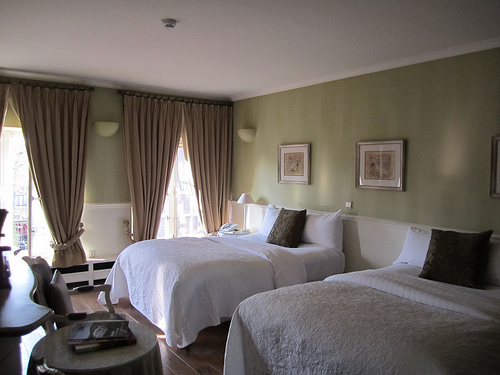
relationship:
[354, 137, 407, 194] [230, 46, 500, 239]
artwork on wall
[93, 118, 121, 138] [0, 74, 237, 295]
light on wall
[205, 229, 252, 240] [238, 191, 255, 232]
table with lamp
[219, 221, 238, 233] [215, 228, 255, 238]
phone on nightstand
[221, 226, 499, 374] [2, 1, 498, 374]
bed in bedroom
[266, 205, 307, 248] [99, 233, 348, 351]
pillow on bed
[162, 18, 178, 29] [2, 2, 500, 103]
sprinkler on ceiling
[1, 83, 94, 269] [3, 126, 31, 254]
curtain on window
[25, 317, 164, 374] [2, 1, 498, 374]
table in bedroom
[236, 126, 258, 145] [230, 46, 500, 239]
light on wall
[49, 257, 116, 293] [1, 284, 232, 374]
radiator near floor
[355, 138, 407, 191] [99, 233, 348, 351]
artwork over bed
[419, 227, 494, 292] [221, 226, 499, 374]
pillow on bed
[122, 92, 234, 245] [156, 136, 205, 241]
curtains over window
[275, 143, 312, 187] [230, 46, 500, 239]
picture on wall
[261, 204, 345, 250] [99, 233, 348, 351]
pillows on bed